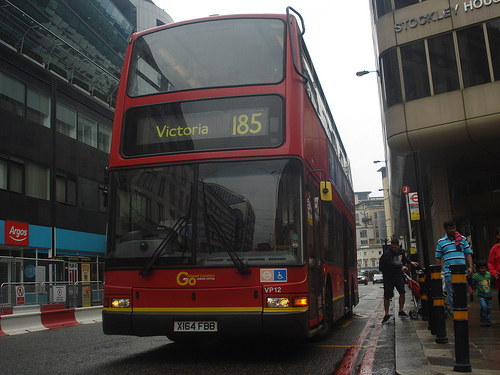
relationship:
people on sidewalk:
[373, 218, 498, 332] [393, 272, 498, 371]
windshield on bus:
[108, 162, 299, 269] [100, 15, 360, 349]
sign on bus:
[151, 110, 273, 144] [100, 15, 360, 349]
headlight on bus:
[262, 296, 289, 313] [82, 84, 385, 362]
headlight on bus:
[107, 294, 132, 315] [82, 84, 385, 362]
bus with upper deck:
[100, 15, 360, 349] [66, 20, 309, 181]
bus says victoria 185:
[100, 15, 360, 349] [152, 109, 266, 140]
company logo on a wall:
[6, 221, 31, 246] [16, 144, 98, 244]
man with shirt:
[434, 218, 473, 315] [435, 234, 473, 276]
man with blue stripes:
[434, 218, 473, 315] [433, 235, 472, 277]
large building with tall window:
[377, 0, 497, 232] [374, 49, 402, 103]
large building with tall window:
[377, 0, 497, 232] [392, 40, 432, 100]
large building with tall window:
[377, 0, 497, 232] [425, 35, 460, 93]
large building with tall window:
[377, 0, 497, 232] [452, 27, 492, 86]